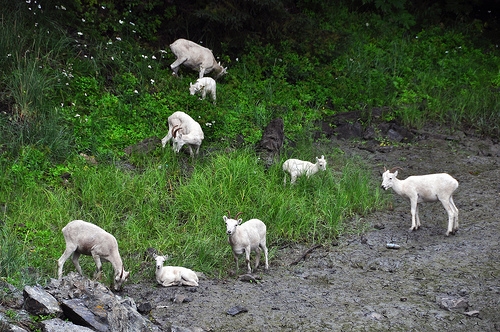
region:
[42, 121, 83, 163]
long green and brown grass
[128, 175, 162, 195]
long green and brown grass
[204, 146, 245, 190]
long green and brown grass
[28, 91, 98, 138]
long green and brown grass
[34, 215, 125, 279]
gray goat in green grass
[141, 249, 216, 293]
gray goat in green grass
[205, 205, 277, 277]
gray goat in green grass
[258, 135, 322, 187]
gray goat in green grass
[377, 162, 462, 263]
gray goat in green grass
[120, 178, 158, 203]
long green and brown grass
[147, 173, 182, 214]
long green and brown grass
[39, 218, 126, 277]
gray goat in green grass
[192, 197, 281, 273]
gray goat in green grass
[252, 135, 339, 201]
gray goat in green grass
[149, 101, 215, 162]
gray goat in green grass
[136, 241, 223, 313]
goat sitting on the ground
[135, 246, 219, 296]
goat sitting on the ground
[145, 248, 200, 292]
goat sitting on the ground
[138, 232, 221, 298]
goat sitting on the ground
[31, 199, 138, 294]
goat sniffing the ground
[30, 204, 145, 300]
goat sniffing the ground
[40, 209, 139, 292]
goat sniffing the ground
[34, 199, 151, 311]
goat sniffing the ground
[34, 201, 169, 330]
goat sniffing the ground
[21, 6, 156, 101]
white flowers on the ground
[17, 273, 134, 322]
rocks on the ground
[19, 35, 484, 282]
goats on a hill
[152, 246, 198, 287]
a white goat laying down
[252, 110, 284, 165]
a tree trunk on the ground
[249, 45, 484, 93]
bushes on the ground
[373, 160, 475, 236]
a white goat standing on the dirt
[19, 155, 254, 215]
tall grass in front of the goats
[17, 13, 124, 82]
flowers and weeds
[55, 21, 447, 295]
white sheep on hill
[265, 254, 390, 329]
brown dirt at base of hill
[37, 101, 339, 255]
green grass on hill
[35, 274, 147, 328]
grey rocks at base of hill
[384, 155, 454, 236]
sheep have white fur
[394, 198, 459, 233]
sheep have white legs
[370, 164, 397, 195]
white face on sheep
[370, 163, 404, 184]
small white horns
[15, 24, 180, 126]
tall grass toward top of hill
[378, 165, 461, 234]
A small white goat.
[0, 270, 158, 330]
A small pile of rocks.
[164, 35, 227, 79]
A white goat eating grass.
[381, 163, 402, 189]
A small white animal head.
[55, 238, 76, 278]
A right hind leg.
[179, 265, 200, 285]
The back half of an animal.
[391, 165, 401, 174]
An ear on a goat.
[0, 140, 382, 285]
A patch of green grass.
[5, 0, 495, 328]
Exterior view, daytime, summer, likely.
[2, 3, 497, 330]
Country area with animals.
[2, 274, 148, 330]
Rocky outcrop, alongside dirt.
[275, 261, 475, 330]
Grey, wet-looking dirt.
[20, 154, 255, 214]
Overgrown, healthy, green grass.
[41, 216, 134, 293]
Grazing goat, near rocks.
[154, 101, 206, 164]
Twisting goat, with horns.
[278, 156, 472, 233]
Small and medium sized goat.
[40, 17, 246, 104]
Large, bending goat and small goat, near blooms and grass.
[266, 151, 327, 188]
a small white baby goat